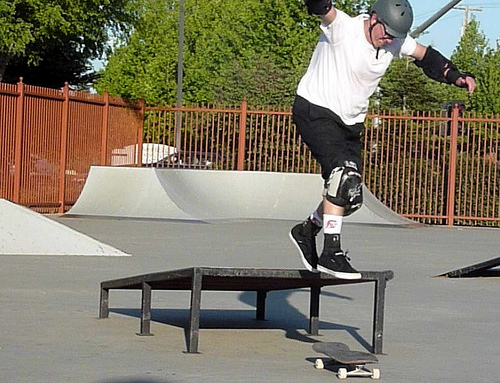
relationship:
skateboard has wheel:
[308, 337, 383, 381] [308, 355, 327, 373]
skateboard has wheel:
[308, 337, 383, 381] [334, 365, 350, 381]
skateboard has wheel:
[308, 337, 383, 381] [367, 365, 383, 382]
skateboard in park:
[308, 337, 383, 381] [3, 163, 499, 382]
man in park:
[281, 1, 479, 277] [3, 163, 499, 382]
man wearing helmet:
[281, 1, 479, 277] [362, 0, 414, 40]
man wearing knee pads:
[281, 1, 479, 277] [323, 163, 364, 207]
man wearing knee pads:
[281, 1, 479, 277] [344, 182, 371, 221]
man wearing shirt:
[281, 1, 479, 277] [291, 5, 417, 127]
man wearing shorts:
[281, 1, 479, 277] [276, 92, 378, 179]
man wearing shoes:
[281, 1, 479, 277] [314, 247, 363, 283]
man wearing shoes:
[281, 1, 479, 277] [286, 219, 321, 285]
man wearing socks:
[281, 1, 479, 277] [320, 211, 345, 239]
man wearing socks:
[281, 1, 479, 277] [306, 207, 323, 233]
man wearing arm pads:
[281, 1, 479, 277] [413, 45, 459, 85]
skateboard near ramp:
[308, 337, 383, 381] [94, 263, 393, 360]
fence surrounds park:
[0, 81, 498, 230] [3, 163, 499, 382]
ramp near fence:
[60, 151, 427, 230] [0, 81, 498, 230]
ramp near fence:
[1, 190, 140, 264] [0, 81, 498, 230]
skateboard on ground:
[308, 337, 383, 381] [4, 225, 499, 377]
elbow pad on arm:
[413, 45, 459, 85] [402, 31, 478, 94]